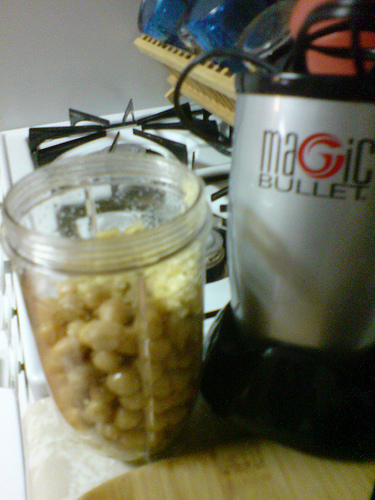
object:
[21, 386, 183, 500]
counter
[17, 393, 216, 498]
table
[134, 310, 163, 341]
corn kernels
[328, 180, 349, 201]
letter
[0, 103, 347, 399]
counter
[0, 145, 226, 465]
container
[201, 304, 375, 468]
base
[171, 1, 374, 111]
cord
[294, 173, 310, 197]
letter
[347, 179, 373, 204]
letter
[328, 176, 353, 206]
letter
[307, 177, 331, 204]
letter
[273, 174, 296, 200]
letter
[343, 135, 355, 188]
black letter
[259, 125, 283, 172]
letter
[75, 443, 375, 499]
board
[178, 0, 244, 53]
blue cups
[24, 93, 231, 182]
burners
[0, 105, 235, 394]
oven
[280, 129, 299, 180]
letter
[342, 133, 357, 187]
letter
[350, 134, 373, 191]
letter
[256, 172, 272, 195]
letter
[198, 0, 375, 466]
appliance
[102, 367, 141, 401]
nuts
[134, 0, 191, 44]
cup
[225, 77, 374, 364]
blender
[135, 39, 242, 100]
shelf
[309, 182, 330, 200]
letter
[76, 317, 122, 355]
corn